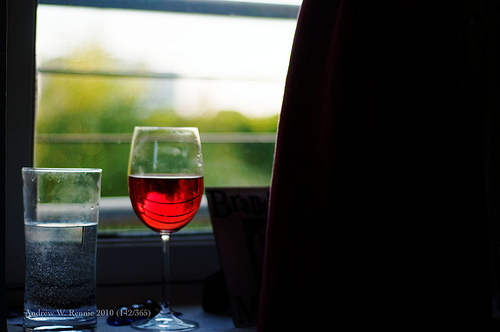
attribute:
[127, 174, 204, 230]
wine — red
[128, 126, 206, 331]
glass — clear, half full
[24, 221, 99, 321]
water — bubbly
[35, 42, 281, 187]
trees — green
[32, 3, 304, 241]
window — closed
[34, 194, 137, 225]
bar — metal, silver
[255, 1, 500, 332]
chair — dark, red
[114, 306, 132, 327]
bead — blue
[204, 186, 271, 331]
frame — white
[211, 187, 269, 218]
letters — black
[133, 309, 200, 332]
base — round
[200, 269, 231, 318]
support — black, cardboard